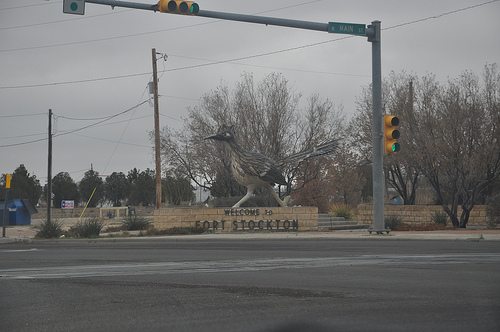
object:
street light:
[385, 115, 402, 128]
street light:
[159, 0, 179, 14]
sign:
[326, 21, 368, 35]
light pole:
[151, 47, 164, 206]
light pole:
[46, 108, 53, 224]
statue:
[201, 124, 340, 208]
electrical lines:
[0, 0, 499, 91]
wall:
[33, 206, 320, 231]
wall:
[358, 201, 500, 230]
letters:
[232, 220, 239, 231]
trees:
[41, 170, 83, 211]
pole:
[368, 18, 391, 234]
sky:
[0, 0, 500, 208]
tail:
[276, 137, 346, 167]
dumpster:
[6, 197, 40, 225]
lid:
[21, 198, 39, 215]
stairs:
[317, 210, 369, 231]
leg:
[232, 183, 257, 209]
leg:
[267, 184, 290, 208]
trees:
[389, 79, 500, 233]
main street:
[0, 235, 500, 331]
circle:
[69, 2, 78, 12]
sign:
[62, 1, 85, 15]